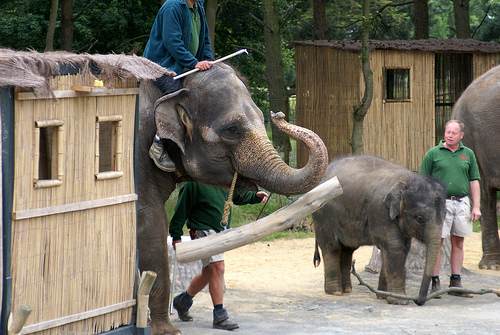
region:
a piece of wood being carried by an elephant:
[148, 180, 353, 260]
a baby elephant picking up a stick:
[313, 152, 459, 315]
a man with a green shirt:
[412, 113, 483, 314]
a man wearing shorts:
[411, 109, 493, 305]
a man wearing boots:
[404, 105, 486, 319]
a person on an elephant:
[136, 5, 237, 173]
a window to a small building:
[30, 118, 77, 206]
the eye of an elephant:
[217, 102, 244, 154]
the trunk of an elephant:
[244, 103, 332, 218]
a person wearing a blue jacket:
[128, 2, 228, 179]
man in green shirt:
[426, 120, 479, 295]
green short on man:
[422, 141, 479, 199]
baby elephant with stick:
[298, 155, 436, 302]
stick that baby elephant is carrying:
[345, 259, 497, 306]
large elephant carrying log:
[157, 62, 344, 259]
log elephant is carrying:
[176, 178, 338, 258]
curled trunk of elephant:
[240, 110, 329, 192]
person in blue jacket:
[146, 0, 212, 85]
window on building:
[379, 63, 417, 108]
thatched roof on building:
[1, 43, 168, 96]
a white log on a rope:
[171, 175, 344, 275]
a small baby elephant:
[292, 145, 442, 295]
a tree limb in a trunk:
[337, 280, 488, 305]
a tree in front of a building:
[345, 0, 390, 145]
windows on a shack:
[12, 110, 129, 200]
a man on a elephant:
[142, 7, 212, 102]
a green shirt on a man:
[428, 145, 474, 198]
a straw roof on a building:
[5, 55, 147, 94]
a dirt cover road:
[282, 296, 459, 324]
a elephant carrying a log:
[145, 39, 322, 296]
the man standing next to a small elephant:
[418, 118, 480, 297]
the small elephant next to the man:
[313, 153, 446, 305]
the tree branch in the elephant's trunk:
[347, 257, 499, 302]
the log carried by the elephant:
[174, 176, 341, 263]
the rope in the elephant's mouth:
[222, 170, 239, 223]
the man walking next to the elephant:
[170, 182, 267, 332]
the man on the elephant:
[142, 0, 215, 96]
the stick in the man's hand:
[172, 48, 248, 80]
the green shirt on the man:
[421, 139, 479, 196]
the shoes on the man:
[431, 275, 475, 299]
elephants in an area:
[71, 1, 479, 333]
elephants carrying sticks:
[79, 23, 496, 333]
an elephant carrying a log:
[90, 52, 368, 301]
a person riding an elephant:
[84, 11, 329, 326]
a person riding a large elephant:
[116, 2, 344, 307]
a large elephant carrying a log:
[104, 51, 300, 279]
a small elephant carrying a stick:
[303, 128, 498, 318]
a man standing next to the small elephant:
[332, 108, 497, 319]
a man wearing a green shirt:
[366, 91, 497, 263]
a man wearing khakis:
[380, 104, 497, 280]